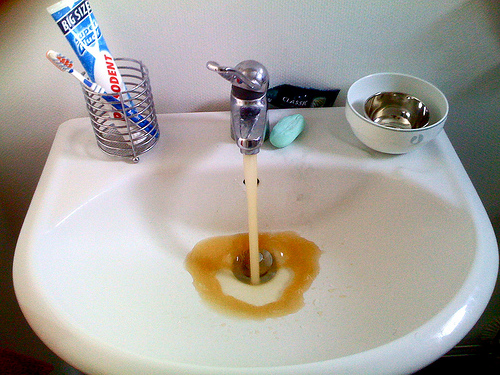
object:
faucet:
[206, 60, 271, 156]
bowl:
[362, 89, 432, 131]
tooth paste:
[45, 0, 148, 146]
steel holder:
[80, 57, 159, 162]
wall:
[413, 142, 473, 189]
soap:
[269, 113, 306, 148]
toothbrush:
[45, 49, 161, 139]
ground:
[378, 196, 396, 219]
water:
[181, 228, 323, 323]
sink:
[11, 105, 499, 375]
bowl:
[344, 72, 450, 155]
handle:
[206, 59, 270, 99]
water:
[233, 147, 267, 292]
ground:
[313, 164, 365, 211]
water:
[184, 155, 326, 317]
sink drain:
[232, 247, 277, 286]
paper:
[267, 84, 342, 110]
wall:
[3, 1, 494, 373]